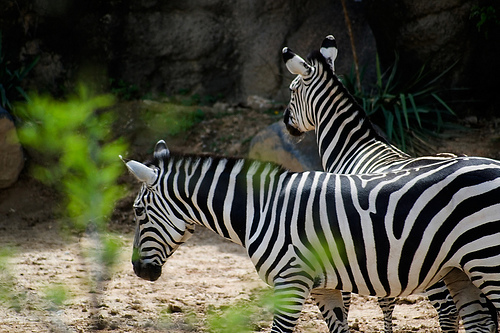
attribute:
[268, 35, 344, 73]
ears — alert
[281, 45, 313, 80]
ear — black, white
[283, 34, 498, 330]
zebra — white, black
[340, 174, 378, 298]
stripe — black, white